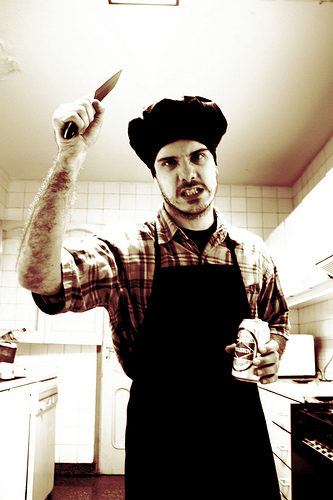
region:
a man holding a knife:
[34, 56, 260, 272]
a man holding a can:
[143, 94, 299, 387]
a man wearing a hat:
[115, 86, 233, 203]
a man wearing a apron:
[106, 142, 261, 384]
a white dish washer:
[22, 361, 69, 449]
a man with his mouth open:
[151, 120, 230, 233]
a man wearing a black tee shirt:
[142, 111, 247, 248]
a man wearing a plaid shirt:
[102, 185, 251, 304]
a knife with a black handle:
[55, 57, 136, 158]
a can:
[214, 305, 289, 390]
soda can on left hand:
[235, 318, 276, 386]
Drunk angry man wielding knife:
[156, 137, 271, 493]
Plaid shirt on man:
[78, 220, 218, 293]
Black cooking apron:
[114, 240, 274, 496]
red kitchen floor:
[40, 443, 123, 494]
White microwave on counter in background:
[263, 323, 328, 382]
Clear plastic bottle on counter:
[4, 321, 28, 342]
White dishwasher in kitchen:
[31, 388, 80, 498]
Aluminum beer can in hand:
[227, 313, 283, 397]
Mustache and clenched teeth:
[178, 180, 220, 203]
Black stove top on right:
[275, 397, 327, 462]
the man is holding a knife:
[55, 54, 243, 392]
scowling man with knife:
[20, 63, 273, 319]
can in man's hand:
[229, 314, 277, 387]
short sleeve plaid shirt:
[49, 213, 290, 347]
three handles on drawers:
[273, 405, 291, 492]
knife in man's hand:
[53, 64, 128, 150]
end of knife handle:
[57, 115, 82, 144]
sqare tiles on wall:
[228, 188, 273, 219]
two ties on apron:
[150, 244, 247, 277]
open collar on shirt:
[156, 206, 241, 257]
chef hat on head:
[131, 95, 230, 179]